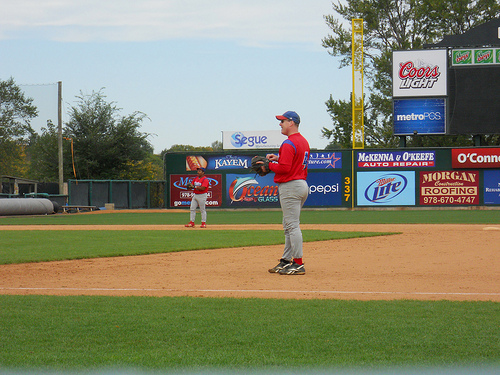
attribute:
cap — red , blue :
[275, 110, 300, 127]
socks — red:
[290, 243, 302, 270]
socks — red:
[275, 250, 292, 265]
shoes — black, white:
[259, 251, 311, 286]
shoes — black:
[264, 255, 308, 277]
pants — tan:
[277, 183, 309, 260]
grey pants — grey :
[267, 177, 318, 272]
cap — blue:
[281, 111, 303, 123]